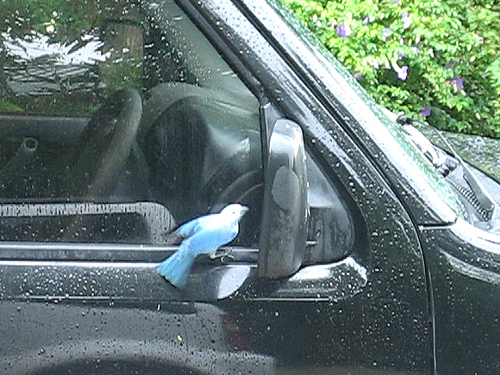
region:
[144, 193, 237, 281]
Bird on a car door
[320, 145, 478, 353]
Rain on a car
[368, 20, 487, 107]
Purple flowers on bushes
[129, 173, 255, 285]
Blue bird on the side of a car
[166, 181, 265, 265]
Car looking in the mirror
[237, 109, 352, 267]
Mirror on a car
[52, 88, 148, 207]
Steering wheel in a car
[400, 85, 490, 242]
windshield wiper on a car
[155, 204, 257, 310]
Blue bird on a car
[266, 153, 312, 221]
Paint peeling off a mirror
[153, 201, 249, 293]
A bird on a car.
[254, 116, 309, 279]
A cars side mirror.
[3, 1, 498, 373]
A car with water on it.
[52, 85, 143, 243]
A cars steering wheel.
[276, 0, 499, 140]
Bushes in the background.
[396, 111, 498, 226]
A cars windshield wiper.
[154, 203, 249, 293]
A white bird on a car.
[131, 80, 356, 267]
A cars dash board.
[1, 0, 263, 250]
A cars side window.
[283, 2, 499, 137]
Flowers on a bush.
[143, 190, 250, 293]
a blue bird on a window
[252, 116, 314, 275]
a black mirror on car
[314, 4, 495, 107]
a green and purple bush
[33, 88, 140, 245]
a black steerling wheel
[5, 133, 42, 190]
a window knob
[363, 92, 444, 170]
a windshield wiper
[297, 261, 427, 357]
rain drops on a panel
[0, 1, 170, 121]
reflection in a window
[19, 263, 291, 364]
a reflection in a door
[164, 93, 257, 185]
a black dash in a car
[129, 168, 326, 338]
This is a small blue bird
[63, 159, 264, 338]
This is a picture of a bird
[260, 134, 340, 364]
This is a car mirror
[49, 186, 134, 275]
This is a window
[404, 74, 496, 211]
This is a wiper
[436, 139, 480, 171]
This is a car hood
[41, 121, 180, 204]
This is a steering wheel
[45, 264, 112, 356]
This is a car door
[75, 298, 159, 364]
The car is painted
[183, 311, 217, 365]
The car is green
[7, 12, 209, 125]
The glare of the leaves are in the window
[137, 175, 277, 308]
A bird is on the window sill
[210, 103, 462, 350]
A bird is next to the side mirror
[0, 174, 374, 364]
Water is on the car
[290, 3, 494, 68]
The car is next to trees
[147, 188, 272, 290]
The bird is small and blue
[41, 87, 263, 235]
The car has a steering wheel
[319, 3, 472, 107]
Purple flowers are on the trees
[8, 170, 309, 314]
A car's reflection is in the window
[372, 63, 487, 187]
The windshield wiper blade